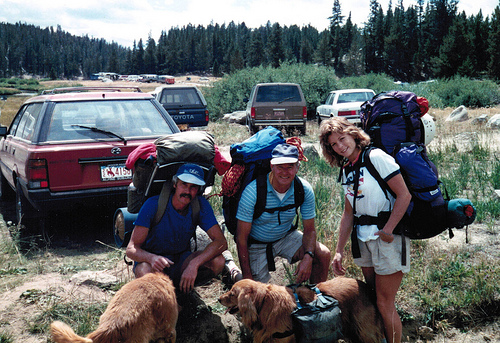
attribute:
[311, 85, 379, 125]
car — white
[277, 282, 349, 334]
bag — gray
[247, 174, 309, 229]
shirt — blue, white, stripes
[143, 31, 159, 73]
pine tree — green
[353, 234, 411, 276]
shorts — tan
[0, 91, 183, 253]
car — red 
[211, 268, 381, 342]
dog — with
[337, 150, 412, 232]
shirt — white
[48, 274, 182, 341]
dog — golden 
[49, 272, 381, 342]
dogs — brown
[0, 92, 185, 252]
station wagon — red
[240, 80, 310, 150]
station wagon — light brown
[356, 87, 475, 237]
gear — blue , black 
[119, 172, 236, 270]
shirt — blue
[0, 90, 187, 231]
car — red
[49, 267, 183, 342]
retriever — golden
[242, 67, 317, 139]
van — brown 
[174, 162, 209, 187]
cap — blue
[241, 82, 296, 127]
toyota truck — dark 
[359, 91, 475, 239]
backpack — big 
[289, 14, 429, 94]
trees — green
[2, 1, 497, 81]
forest — conifers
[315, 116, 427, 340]
woman — young , white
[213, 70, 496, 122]
shrubbery — green 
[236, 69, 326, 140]
vehicle — brown, sports, utility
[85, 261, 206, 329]
dog — brown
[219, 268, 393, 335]
dog — brown